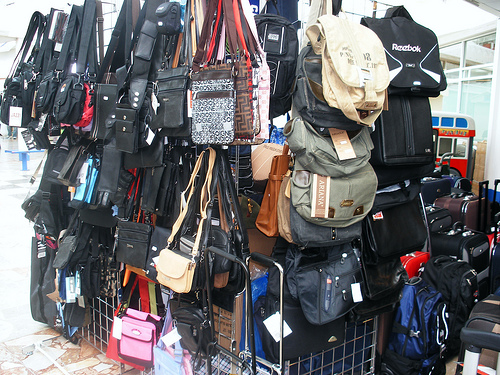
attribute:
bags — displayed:
[6, 5, 498, 367]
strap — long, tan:
[161, 139, 224, 255]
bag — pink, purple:
[111, 302, 164, 367]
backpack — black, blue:
[387, 272, 455, 365]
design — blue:
[186, 63, 240, 147]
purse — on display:
[4, 5, 270, 373]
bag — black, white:
[363, 2, 451, 99]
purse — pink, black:
[115, 301, 165, 364]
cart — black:
[201, 239, 274, 373]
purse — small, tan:
[149, 245, 199, 295]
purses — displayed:
[1, 1, 453, 373]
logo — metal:
[324, 331, 342, 344]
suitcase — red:
[395, 248, 437, 287]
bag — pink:
[115, 302, 163, 362]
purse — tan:
[143, 141, 223, 299]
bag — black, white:
[356, 1, 451, 101]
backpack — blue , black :
[271, 83, 421, 335]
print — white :
[275, 155, 361, 280]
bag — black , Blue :
[170, 99, 423, 310]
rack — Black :
[254, 3, 478, 203]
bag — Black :
[229, 128, 431, 279]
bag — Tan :
[282, 100, 389, 267]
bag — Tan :
[187, 57, 240, 139]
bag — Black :
[164, 75, 303, 212]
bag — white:
[283, 113, 408, 277]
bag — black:
[374, 53, 430, 195]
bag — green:
[253, 104, 364, 204]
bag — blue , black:
[233, 80, 399, 273]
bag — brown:
[365, 35, 465, 243]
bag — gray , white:
[284, 20, 404, 260]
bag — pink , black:
[64, 253, 196, 365]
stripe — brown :
[242, 237, 311, 366]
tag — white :
[243, 282, 316, 350]